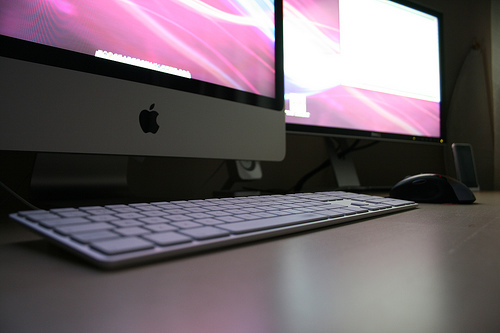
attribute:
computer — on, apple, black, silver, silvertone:
[0, 4, 288, 160]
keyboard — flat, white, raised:
[14, 186, 422, 274]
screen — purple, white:
[276, 3, 448, 142]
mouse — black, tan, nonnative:
[377, 172, 476, 207]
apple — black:
[136, 107, 163, 136]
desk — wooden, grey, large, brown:
[2, 184, 500, 328]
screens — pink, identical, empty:
[0, 1, 465, 164]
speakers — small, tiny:
[452, 144, 477, 188]